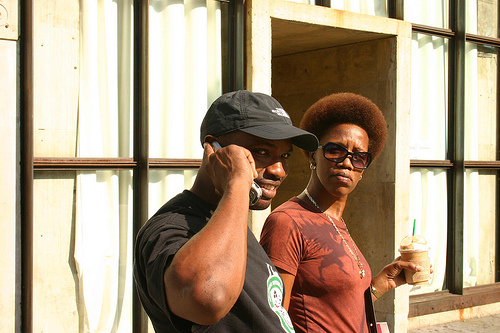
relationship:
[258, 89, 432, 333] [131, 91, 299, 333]
afro with person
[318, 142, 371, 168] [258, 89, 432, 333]
sunglasses on afro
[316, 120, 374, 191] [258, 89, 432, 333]
face of afro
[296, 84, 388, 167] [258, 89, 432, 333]
afro of afro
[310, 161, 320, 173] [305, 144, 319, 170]
earring on right ear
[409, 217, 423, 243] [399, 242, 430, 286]
straw in drink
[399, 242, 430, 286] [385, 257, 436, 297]
drink in hand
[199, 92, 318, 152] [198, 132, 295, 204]
hat on head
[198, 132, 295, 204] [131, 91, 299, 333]
head of person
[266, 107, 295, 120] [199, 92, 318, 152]
logo on hat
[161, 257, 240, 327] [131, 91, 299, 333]
right elbow of person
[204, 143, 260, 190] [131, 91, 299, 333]
right hand of person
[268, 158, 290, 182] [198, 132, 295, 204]
nose of head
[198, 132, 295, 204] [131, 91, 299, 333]
head of a person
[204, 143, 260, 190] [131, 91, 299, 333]
right hand of a person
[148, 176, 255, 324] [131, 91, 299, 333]
arm of a person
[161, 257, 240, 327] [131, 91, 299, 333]
right elbow of a person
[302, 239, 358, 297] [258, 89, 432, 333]
breast of a afro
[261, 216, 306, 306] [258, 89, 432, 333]
arm of a afro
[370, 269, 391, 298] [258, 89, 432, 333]
wrist of afro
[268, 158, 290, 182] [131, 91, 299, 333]
nose of person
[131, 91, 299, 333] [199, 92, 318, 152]
person wearing a hat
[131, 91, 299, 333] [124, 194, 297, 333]
person wearing shirt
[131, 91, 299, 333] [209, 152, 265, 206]
person using cellphone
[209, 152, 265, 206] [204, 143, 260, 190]
cellphone in h right hand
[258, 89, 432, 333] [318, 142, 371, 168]
afro wearing sunglasses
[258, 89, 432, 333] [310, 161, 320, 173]
afro wearing earring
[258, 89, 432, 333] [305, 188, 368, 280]
afro wearing necklace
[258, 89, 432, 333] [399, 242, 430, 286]
afro holding drink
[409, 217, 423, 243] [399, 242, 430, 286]
straw inside drink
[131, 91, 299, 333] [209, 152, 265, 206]
person with cellphone